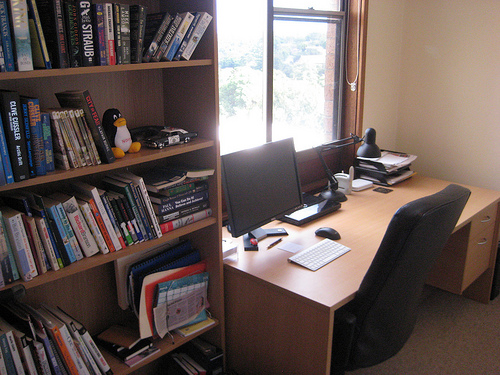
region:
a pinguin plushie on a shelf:
[98, 97, 150, 171]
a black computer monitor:
[219, 147, 308, 220]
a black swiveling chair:
[341, 175, 471, 357]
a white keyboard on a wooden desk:
[284, 240, 347, 277]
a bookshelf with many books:
[6, 0, 206, 265]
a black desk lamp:
[322, 130, 384, 211]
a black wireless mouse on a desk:
[313, 219, 342, 242]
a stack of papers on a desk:
[364, 146, 429, 188]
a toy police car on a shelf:
[149, 122, 210, 148]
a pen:
[266, 238, 284, 255]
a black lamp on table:
[278, 137, 355, 223]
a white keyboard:
[289, 237, 352, 273]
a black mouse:
[308, 217, 339, 239]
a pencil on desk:
[261, 234, 288, 251]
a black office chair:
[328, 178, 492, 369]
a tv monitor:
[223, 134, 305, 244]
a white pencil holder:
[326, 170, 359, 191]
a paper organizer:
[354, 140, 422, 191]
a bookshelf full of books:
[0, 13, 221, 373]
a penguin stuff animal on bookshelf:
[102, 97, 139, 157]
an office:
[10, 2, 493, 369]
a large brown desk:
[221, 165, 496, 371]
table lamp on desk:
[312, 116, 378, 209]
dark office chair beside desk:
[335, 167, 475, 372]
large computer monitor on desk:
[216, 125, 306, 255]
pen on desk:
[255, 226, 285, 256]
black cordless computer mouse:
[300, 216, 360, 241]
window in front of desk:
[217, 2, 392, 233]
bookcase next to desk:
[0, 0, 291, 371]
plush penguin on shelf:
[90, 95, 145, 165]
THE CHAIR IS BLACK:
[371, 298, 388, 317]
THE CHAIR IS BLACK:
[361, 325, 385, 340]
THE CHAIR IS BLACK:
[360, 313, 383, 333]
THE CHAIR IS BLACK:
[359, 331, 376, 343]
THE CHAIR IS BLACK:
[373, 279, 384, 320]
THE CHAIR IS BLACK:
[359, 303, 371, 320]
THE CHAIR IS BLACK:
[363, 322, 377, 348]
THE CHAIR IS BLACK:
[374, 318, 389, 343]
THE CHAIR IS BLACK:
[372, 316, 384, 331]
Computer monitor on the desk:
[221, 136, 301, 251]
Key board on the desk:
[288, 237, 350, 271]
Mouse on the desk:
[315, 225, 342, 240]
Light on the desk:
[311, 126, 381, 200]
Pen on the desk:
[266, 236, 281, 250]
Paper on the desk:
[276, 238, 301, 252]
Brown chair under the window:
[221, 161, 496, 372]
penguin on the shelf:
[102, 105, 141, 157]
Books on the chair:
[8, 1, 217, 373]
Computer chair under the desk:
[339, 182, 472, 367]